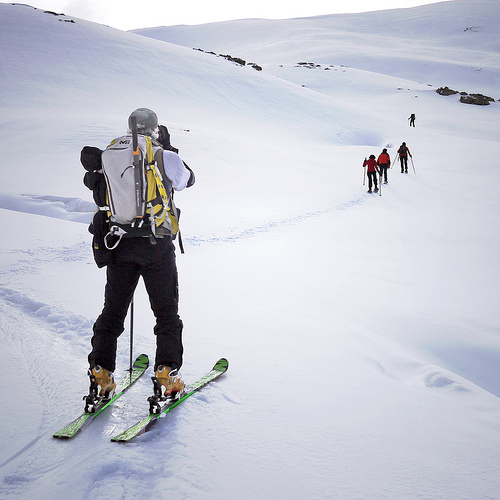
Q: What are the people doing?
A: Skiing.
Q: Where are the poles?
A: On the person's feet.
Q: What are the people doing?
A: Skiing.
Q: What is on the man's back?
A: Backpack.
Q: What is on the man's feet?
A: Skis.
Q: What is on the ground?
A: Snow.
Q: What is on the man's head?
A: Hat.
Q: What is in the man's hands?
A: Ski pole.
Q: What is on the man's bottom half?
A: Pants.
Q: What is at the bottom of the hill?
A: Rocks.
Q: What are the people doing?
A: Skiing.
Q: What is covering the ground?
A: Snow.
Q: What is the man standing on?
A: Skis.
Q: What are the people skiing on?
A: Hills.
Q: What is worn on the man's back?
A: Bag.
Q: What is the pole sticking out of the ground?
A: Ski pole.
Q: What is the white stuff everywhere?
A: Snow.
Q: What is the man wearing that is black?
A: Pants.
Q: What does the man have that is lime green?
A: Skis.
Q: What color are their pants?
A: Black.